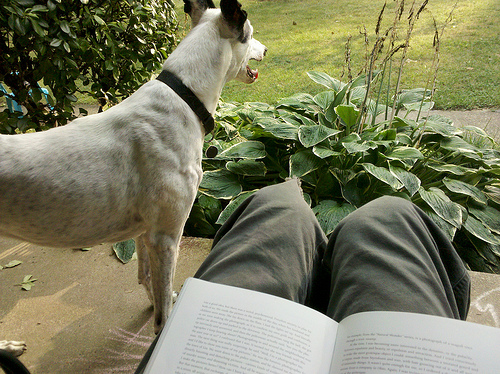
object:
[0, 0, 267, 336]
dog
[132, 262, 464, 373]
lap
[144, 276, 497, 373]
book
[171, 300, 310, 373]
text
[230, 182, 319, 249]
knee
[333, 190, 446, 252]
knee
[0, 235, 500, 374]
porch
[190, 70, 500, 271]
plant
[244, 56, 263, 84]
mouth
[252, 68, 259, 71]
teeth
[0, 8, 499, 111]
yard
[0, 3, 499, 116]
lawn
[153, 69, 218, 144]
collar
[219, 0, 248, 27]
ear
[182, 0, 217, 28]
ear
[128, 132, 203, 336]
front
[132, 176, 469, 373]
person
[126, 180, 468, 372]
pants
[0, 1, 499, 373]
ground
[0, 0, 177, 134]
shrubbery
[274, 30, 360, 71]
shadow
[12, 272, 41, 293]
leaf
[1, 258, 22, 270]
leaf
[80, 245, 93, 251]
leaf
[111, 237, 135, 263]
leaf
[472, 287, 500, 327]
mark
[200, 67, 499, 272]
leafy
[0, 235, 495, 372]
concrete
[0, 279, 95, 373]
concrete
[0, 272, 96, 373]
tan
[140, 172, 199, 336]
leg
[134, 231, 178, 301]
leg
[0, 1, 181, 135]
bush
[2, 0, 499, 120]
grass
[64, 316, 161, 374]
drawings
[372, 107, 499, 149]
sidewalk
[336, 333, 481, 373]
words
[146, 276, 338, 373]
pages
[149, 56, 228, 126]
neck